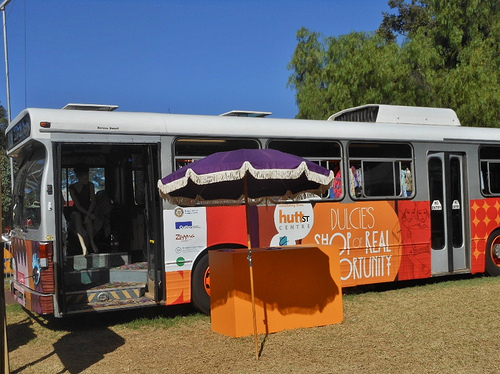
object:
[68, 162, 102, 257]
person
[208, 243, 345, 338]
booth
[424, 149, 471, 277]
door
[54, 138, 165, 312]
door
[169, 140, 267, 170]
window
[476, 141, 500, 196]
window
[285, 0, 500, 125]
tree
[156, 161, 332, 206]
fringe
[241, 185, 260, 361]
pole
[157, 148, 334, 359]
purple umbrella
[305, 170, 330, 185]
white fringe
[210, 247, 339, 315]
shadow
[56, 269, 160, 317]
step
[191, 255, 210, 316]
wheel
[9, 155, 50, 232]
window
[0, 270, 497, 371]
grass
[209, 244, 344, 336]
stand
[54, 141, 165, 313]
front windows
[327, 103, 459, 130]
unit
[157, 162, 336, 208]
trim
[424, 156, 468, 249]
window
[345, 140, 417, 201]
window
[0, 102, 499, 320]
bus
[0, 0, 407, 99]
blue sky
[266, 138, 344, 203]
window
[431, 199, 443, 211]
white sign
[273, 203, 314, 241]
white sign